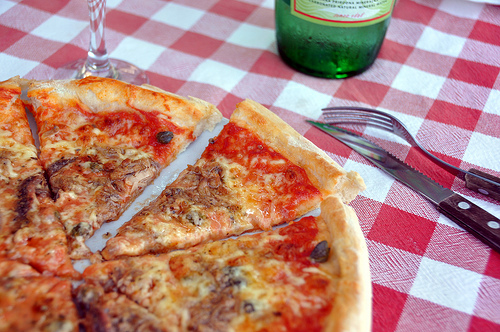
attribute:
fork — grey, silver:
[327, 104, 484, 180]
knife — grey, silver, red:
[316, 121, 492, 241]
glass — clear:
[275, 1, 387, 79]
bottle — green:
[267, 0, 390, 72]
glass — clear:
[77, 5, 143, 75]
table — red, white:
[4, 5, 462, 214]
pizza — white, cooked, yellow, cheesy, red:
[6, 75, 287, 331]